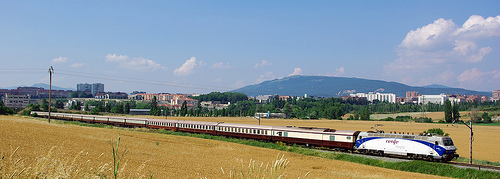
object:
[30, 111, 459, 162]
train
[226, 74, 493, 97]
mountain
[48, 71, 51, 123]
pole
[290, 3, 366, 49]
sky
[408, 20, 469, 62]
clouds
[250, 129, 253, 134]
windows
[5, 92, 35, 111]
buildings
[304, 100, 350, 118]
trees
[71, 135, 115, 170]
field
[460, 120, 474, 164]
lamp post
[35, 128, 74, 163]
grass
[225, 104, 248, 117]
shrubs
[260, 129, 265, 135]
compartment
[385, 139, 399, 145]
logo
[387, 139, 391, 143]
letters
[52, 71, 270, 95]
wires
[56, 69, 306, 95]
electrice lines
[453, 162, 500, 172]
tracks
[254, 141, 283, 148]
plants